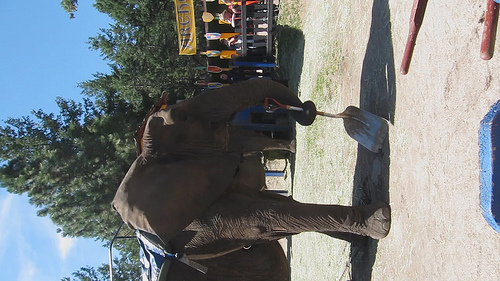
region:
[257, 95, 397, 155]
a shovel held by an elephant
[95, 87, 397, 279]
an elephant holding a shovel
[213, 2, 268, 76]
people watching the elephant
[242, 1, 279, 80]
a fence separating the people from the elephant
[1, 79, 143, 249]
the tallest tree in the photo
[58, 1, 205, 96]
trees growing in the background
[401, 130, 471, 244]
sand and dirt in the elephant enclosure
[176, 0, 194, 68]
a yellow banner above the people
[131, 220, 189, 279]
a saddle or blanket worn by the elephant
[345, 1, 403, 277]
the elephant's shadow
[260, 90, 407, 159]
Dirty shovel held by elephant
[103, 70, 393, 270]
Elephant holding shovel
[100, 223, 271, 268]
Harness on elephant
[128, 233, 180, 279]
Blue seat on elephant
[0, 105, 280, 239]
Tall green tree behind elephant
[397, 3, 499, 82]
Brownish red wooden handles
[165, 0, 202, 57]
Yellow and blue arctic sign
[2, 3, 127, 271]
Bright blue sky with wispy clouds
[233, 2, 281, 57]
Grey fencing rails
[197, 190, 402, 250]
Wrinkly grey skin on elephant's leg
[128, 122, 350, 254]
grey color elephant.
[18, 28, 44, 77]
sky is blue color.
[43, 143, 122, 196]
trees are green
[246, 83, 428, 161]
elephant is holding digger.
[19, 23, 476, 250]
daytime picture.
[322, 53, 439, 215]
shadow falls in the ground.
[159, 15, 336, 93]
shop is in the sides of the road.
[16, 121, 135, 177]
trees are behind the elephant.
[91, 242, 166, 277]
coach is tied at the back of the elephant.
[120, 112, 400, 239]
one elephant is seen.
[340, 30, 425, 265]
Shadow is in the ground.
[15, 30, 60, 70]
sky is blue.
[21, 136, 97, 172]
leaves are green.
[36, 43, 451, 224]
picture is taken during daytime.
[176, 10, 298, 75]
shops are behind the elephant.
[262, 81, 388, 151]
elephant is holding the digger.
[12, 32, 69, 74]
day is sunny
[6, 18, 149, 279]
trees are behind the elephant.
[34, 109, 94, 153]
section of green tree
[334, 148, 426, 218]
shadow of large elephant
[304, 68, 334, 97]
patch of green grass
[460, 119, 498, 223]
wide blue object on ground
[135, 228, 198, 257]
blue seat on elephant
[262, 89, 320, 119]
large elephant tusk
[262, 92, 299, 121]
handle of silver shovel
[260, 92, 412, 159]
silver shovel with red handle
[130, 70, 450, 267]
large brown elephant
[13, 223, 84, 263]
white clouds in the blue skies